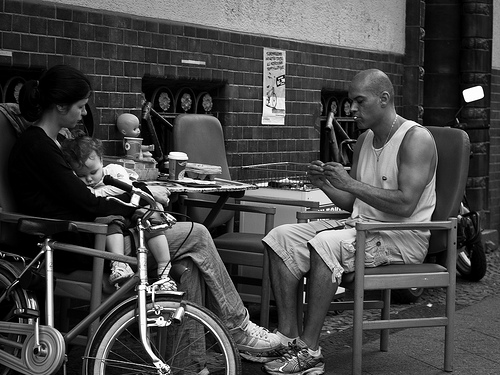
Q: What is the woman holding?
A: The baby.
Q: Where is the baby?
A: In the woman's lap.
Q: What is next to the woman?
A: The bicycle.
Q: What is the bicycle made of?
A: Metal.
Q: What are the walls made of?
A: Brick.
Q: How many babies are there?
A: One.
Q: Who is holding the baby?
A: The woman.